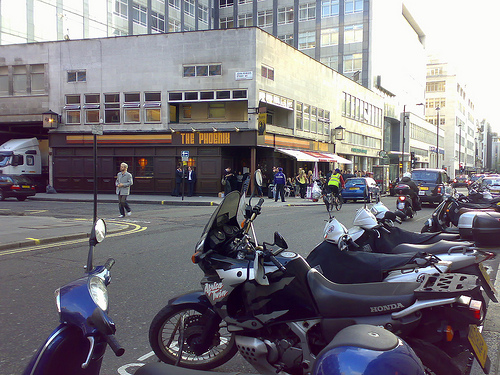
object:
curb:
[0, 215, 129, 251]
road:
[0, 195, 500, 375]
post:
[93, 133, 98, 222]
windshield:
[195, 190, 242, 254]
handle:
[104, 334, 125, 356]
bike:
[19, 218, 424, 375]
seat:
[306, 268, 420, 318]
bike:
[148, 190, 490, 375]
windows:
[65, 93, 161, 125]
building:
[0, 0, 500, 197]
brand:
[370, 302, 405, 312]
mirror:
[254, 170, 263, 186]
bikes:
[305, 196, 500, 303]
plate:
[467, 324, 488, 368]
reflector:
[469, 299, 484, 320]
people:
[328, 168, 345, 206]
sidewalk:
[36, 192, 326, 209]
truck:
[0, 136, 48, 178]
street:
[0, 175, 500, 375]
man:
[115, 162, 133, 217]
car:
[410, 168, 456, 206]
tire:
[148, 298, 238, 370]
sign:
[92, 125, 103, 135]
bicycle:
[323, 188, 342, 212]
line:
[0, 218, 148, 255]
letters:
[181, 133, 231, 145]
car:
[341, 177, 381, 203]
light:
[437, 321, 454, 342]